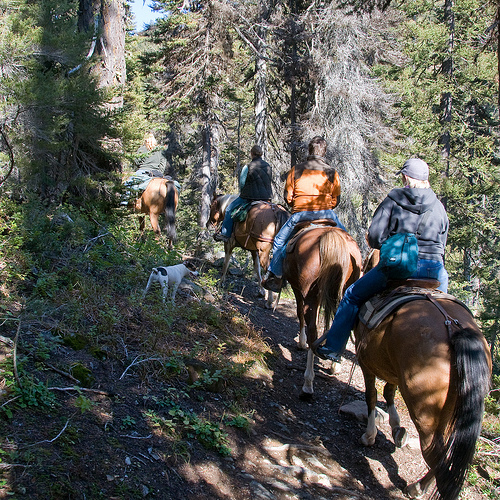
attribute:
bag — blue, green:
[375, 230, 427, 278]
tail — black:
[438, 329, 489, 497]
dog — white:
[137, 246, 207, 308]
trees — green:
[3, 2, 141, 249]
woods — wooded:
[1, 3, 500, 496]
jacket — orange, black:
[283, 161, 345, 220]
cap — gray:
[391, 151, 433, 185]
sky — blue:
[123, 0, 178, 36]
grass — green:
[28, 203, 253, 412]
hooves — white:
[356, 402, 410, 455]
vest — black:
[246, 163, 273, 203]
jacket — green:
[138, 146, 174, 178]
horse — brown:
[351, 291, 496, 499]